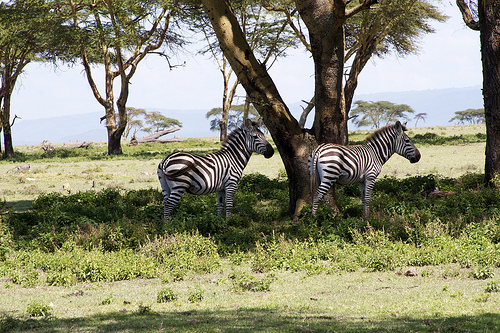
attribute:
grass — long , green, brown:
[25, 178, 157, 273]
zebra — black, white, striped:
[302, 120, 422, 214]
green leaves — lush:
[32, 3, 142, 58]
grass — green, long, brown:
[0, 122, 499, 332]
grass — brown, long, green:
[22, 190, 79, 218]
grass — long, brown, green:
[0, 155, 495, 297]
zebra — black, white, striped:
[143, 115, 278, 221]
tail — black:
[306, 153, 318, 195]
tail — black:
[156, 157, 201, 178]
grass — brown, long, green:
[8, 150, 497, 331]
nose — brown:
[409, 153, 420, 162]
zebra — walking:
[285, 114, 442, 221]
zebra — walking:
[129, 110, 279, 244]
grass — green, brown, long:
[25, 105, 498, 290]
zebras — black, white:
[132, 104, 452, 279]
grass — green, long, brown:
[0, 173, 497, 331]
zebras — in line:
[153, 117, 274, 227]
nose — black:
[265, 145, 275, 158]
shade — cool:
[2, 175, 496, 245]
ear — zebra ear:
[244, 119, 254, 131]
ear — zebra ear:
[254, 114, 266, 129]